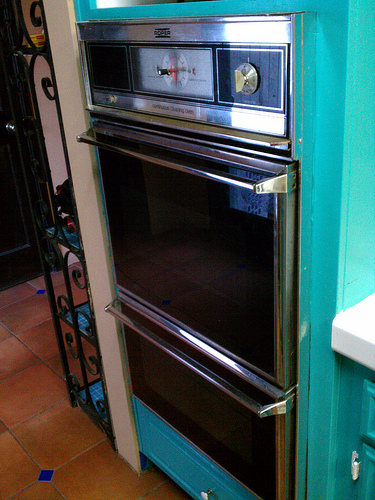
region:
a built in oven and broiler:
[86, 15, 315, 498]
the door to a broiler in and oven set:
[102, 300, 277, 495]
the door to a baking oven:
[72, 125, 309, 379]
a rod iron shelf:
[38, 225, 100, 438]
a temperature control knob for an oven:
[224, 60, 265, 98]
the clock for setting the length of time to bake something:
[132, 40, 219, 100]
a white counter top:
[326, 300, 373, 367]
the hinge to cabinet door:
[346, 452, 363, 485]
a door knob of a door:
[4, 118, 22, 136]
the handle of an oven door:
[74, 127, 271, 202]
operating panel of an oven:
[72, 8, 308, 138]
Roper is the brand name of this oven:
[149, 21, 174, 41]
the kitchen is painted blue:
[300, 2, 373, 499]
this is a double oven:
[81, 12, 301, 495]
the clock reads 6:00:
[126, 41, 218, 101]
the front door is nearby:
[2, 1, 66, 295]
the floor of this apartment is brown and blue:
[1, 261, 219, 497]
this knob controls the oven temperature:
[214, 44, 284, 113]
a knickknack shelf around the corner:
[0, 2, 116, 436]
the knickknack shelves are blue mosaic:
[44, 214, 109, 433]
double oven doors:
[84, 113, 291, 497]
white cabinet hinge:
[350, 449, 358, 482]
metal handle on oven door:
[76, 118, 295, 201]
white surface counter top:
[332, 290, 373, 372]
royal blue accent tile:
[35, 466, 55, 483]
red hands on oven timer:
[156, 46, 195, 91]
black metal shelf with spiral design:
[2, 0, 113, 445]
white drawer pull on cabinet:
[195, 479, 214, 498]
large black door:
[3, 0, 60, 290]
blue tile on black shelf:
[58, 300, 114, 425]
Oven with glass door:
[79, 44, 289, 441]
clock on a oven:
[137, 45, 218, 90]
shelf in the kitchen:
[14, 53, 84, 417]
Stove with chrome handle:
[75, 127, 293, 208]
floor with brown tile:
[17, 356, 86, 474]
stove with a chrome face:
[76, 20, 313, 140]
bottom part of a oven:
[124, 315, 292, 485]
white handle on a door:
[335, 426, 370, 483]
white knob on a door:
[193, 486, 212, 498]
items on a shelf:
[34, 173, 84, 236]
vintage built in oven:
[65, 5, 316, 474]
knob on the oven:
[221, 52, 268, 109]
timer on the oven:
[150, 43, 195, 109]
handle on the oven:
[74, 122, 286, 199]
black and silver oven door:
[84, 120, 318, 384]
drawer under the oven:
[135, 412, 244, 499]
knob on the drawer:
[198, 482, 215, 499]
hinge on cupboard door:
[347, 448, 365, 484]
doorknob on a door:
[4, 112, 29, 145]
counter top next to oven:
[333, 311, 368, 360]